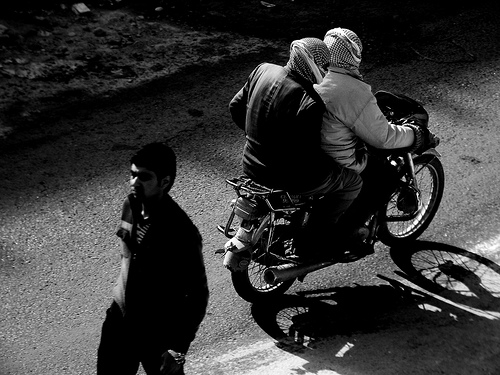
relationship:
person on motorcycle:
[230, 37, 347, 239] [214, 90, 444, 303]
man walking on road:
[97, 141, 215, 374] [0, 34, 499, 372]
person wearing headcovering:
[230, 37, 347, 239] [284, 27, 367, 86]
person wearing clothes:
[230, 37, 347, 239] [230, 62, 366, 242]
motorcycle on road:
[214, 90, 444, 303] [0, 34, 499, 372]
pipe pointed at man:
[256, 262, 309, 284] [97, 141, 215, 374]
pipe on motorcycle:
[256, 262, 309, 284] [214, 90, 444, 303]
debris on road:
[68, 2, 108, 29] [0, 34, 499, 372]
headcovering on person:
[284, 27, 367, 86] [230, 37, 347, 239]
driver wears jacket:
[315, 69, 421, 177] [317, 73, 414, 186]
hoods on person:
[284, 27, 367, 86] [230, 37, 347, 239]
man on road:
[97, 141, 215, 374] [0, 34, 499, 372]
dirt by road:
[4, 3, 396, 84] [0, 34, 499, 372]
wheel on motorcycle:
[219, 230, 307, 304] [214, 90, 444, 303]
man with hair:
[97, 141, 215, 374] [131, 141, 180, 177]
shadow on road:
[241, 242, 497, 374] [0, 34, 499, 372]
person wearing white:
[313, 24, 411, 166] [330, 84, 358, 122]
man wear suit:
[97, 141, 215, 374] [95, 201, 209, 375]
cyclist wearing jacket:
[315, 69, 421, 177] [317, 73, 414, 186]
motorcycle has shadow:
[214, 90, 444, 303] [241, 242, 497, 374]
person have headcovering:
[230, 37, 347, 239] [284, 27, 367, 86]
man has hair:
[97, 141, 215, 374] [131, 141, 180, 177]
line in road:
[346, 241, 490, 343] [0, 34, 499, 372]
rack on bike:
[227, 169, 268, 203] [214, 90, 444, 303]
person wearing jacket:
[230, 37, 347, 239] [317, 73, 414, 186]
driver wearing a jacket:
[315, 69, 421, 177] [317, 73, 414, 174]